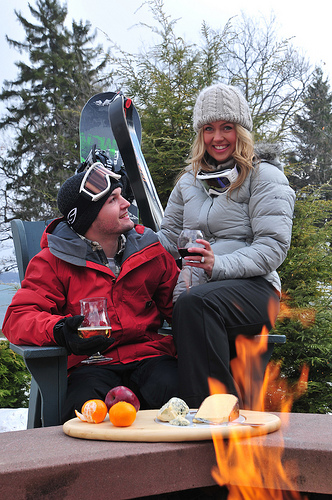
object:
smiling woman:
[154, 83, 294, 410]